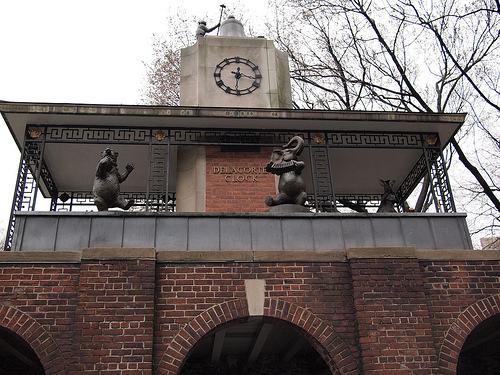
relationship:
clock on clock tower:
[189, 37, 272, 102] [9, 30, 500, 327]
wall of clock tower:
[91, 274, 123, 340] [0, 2, 500, 375]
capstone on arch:
[223, 276, 283, 314] [161, 269, 357, 362]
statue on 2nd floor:
[266, 143, 332, 210] [31, 120, 459, 228]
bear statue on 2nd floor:
[67, 142, 145, 209] [31, 120, 459, 228]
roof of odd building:
[478, 232, 500, 237] [481, 224, 498, 249]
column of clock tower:
[348, 248, 452, 366] [0, 2, 500, 375]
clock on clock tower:
[189, 37, 272, 102] [0, 2, 500, 375]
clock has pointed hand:
[189, 37, 272, 102] [239, 68, 258, 87]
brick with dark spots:
[370, 270, 424, 286] [132, 263, 174, 296]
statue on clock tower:
[172, 0, 289, 44] [9, 30, 500, 327]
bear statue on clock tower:
[67, 142, 145, 209] [9, 30, 500, 327]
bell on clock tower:
[218, 12, 249, 40] [9, 30, 500, 327]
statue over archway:
[172, 0, 289, 44] [161, 269, 357, 362]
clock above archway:
[189, 37, 272, 102] [161, 269, 357, 362]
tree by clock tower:
[287, 4, 499, 101] [0, 2, 500, 375]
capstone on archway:
[223, 276, 283, 314] [161, 269, 357, 362]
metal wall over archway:
[145, 214, 448, 250] [161, 269, 357, 362]